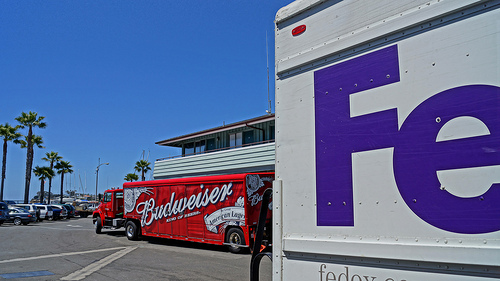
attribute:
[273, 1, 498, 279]
truck — white, large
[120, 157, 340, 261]
truck — red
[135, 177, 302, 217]
letters — white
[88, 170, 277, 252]
semi — large, red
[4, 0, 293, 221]
sky — cloudless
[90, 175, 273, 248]
truck — Red 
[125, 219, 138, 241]
tire — big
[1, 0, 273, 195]
sky — Blue 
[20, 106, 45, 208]
palm tree — tall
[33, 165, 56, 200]
palm tree — tall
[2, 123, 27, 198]
palm tree — tall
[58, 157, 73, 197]
palm tree — tall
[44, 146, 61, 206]
palm tree — tall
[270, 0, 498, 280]
white truck — white 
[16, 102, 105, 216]
trees — palm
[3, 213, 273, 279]
road —  with tarmac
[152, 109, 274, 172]
building — tall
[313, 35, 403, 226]
letter — blue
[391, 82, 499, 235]
letter — blue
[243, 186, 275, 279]
door handle — black